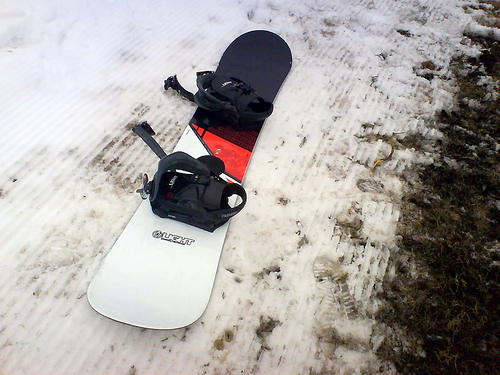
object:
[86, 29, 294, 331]
snow board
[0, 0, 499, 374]
ground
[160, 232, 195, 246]
name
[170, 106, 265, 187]
middle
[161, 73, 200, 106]
strap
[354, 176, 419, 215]
footprint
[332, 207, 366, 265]
foot print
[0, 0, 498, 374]
grass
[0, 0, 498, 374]
outside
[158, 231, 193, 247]
light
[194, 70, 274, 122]
foot straps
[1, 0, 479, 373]
tire track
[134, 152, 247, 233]
places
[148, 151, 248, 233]
feet place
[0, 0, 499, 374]
snow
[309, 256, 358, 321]
feet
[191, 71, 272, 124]
place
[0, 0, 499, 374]
sunny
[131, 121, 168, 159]
straps